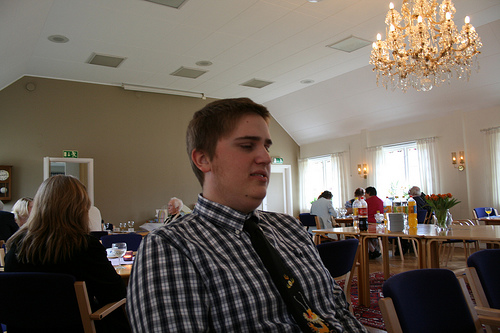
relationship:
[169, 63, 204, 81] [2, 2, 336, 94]
air vent in ceiling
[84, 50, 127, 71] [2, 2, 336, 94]
air vent in ceiling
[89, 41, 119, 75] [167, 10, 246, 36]
vent in the ceiling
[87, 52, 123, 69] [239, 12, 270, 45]
vent in the ceiling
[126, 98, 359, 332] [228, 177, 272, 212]
guy with chin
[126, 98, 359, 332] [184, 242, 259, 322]
guy wearing shirt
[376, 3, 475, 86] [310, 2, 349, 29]
chandelier hanging from ceiling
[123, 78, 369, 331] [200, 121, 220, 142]
guy has hair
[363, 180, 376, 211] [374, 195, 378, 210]
person wearing shirt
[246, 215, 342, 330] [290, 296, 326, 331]
tie with design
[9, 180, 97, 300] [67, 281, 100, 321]
woman sitting in chair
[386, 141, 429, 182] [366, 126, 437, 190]
curtains over the window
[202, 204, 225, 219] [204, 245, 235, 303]
collar of shirt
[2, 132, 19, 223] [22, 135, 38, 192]
clock on wall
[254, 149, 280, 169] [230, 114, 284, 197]
nose on face